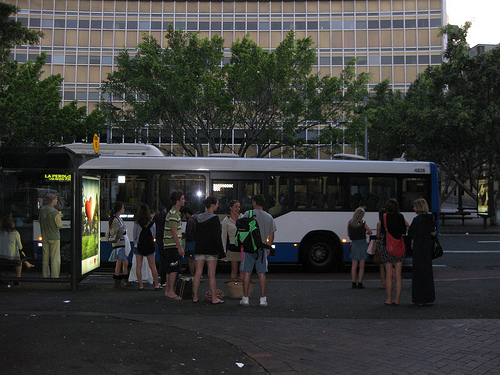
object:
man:
[38, 193, 63, 278]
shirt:
[163, 206, 182, 249]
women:
[372, 207, 403, 288]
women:
[346, 205, 373, 290]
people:
[406, 198, 445, 307]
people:
[105, 202, 132, 290]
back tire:
[301, 236, 339, 273]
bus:
[80, 154, 442, 274]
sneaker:
[259, 297, 267, 308]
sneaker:
[239, 296, 249, 306]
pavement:
[0, 305, 298, 374]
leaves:
[415, 89, 469, 136]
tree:
[97, 20, 399, 155]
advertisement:
[82, 175, 102, 276]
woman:
[379, 198, 409, 307]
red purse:
[384, 213, 407, 257]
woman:
[2, 215, 36, 288]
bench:
[0, 259, 26, 288]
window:
[277, 169, 329, 211]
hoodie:
[194, 212, 226, 260]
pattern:
[233, 319, 498, 375]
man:
[233, 193, 277, 307]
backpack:
[233, 209, 276, 254]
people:
[131, 204, 164, 292]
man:
[163, 191, 186, 300]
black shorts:
[158, 247, 182, 274]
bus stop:
[0, 168, 102, 292]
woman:
[184, 195, 227, 304]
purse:
[431, 237, 444, 260]